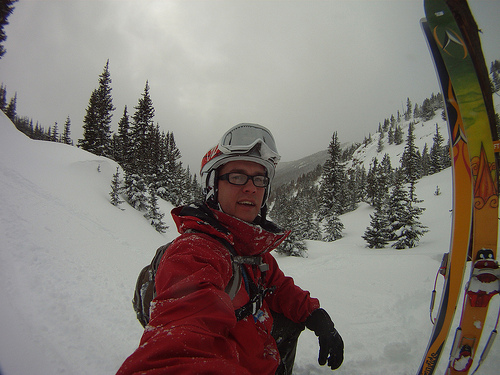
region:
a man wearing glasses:
[212, 117, 297, 227]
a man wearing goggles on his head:
[200, 102, 290, 172]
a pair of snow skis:
[420, 40, 490, 370]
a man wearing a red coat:
[105, 205, 295, 352]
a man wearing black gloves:
[305, 285, 355, 365]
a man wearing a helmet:
[200, 131, 286, 176]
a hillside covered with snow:
[339, 91, 429, 279]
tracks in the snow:
[37, 208, 121, 361]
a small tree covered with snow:
[99, 164, 133, 224]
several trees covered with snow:
[310, 94, 428, 286]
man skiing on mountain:
[100, 98, 383, 373]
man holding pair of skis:
[164, 7, 489, 374]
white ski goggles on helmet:
[207, 124, 287, 169]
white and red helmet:
[198, 148, 226, 171]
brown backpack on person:
[128, 261, 162, 316]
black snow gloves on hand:
[298, 312, 361, 370]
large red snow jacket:
[111, 205, 309, 373]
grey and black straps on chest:
[220, 260, 284, 327]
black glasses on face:
[222, 170, 272, 190]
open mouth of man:
[228, 195, 265, 210]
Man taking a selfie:
[108, 117, 350, 373]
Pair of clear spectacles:
[214, 168, 271, 192]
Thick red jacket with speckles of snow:
[108, 196, 320, 373]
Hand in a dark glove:
[303, 304, 351, 371]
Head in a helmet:
[198, 123, 284, 223]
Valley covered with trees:
[0, 5, 498, 270]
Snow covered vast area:
[2, 98, 469, 373]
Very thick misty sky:
[1, 3, 498, 185]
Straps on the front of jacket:
[116, 231, 312, 373]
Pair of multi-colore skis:
[402, 0, 499, 374]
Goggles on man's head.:
[210, 127, 285, 162]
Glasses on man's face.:
[223, 166, 288, 198]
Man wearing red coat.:
[174, 243, 249, 353]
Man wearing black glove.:
[302, 295, 339, 357]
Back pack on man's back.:
[123, 251, 188, 343]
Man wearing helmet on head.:
[195, 150, 295, 222]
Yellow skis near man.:
[408, 213, 486, 370]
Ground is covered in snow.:
[37, 169, 114, 295]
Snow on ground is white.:
[40, 210, 104, 309]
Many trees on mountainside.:
[115, 128, 190, 209]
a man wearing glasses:
[212, 167, 277, 192]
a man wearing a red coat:
[170, 215, 285, 301]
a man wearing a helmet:
[187, 110, 291, 220]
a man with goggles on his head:
[203, 117, 285, 169]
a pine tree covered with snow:
[71, 54, 120, 159]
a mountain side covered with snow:
[345, 92, 429, 222]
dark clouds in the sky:
[114, 23, 351, 65]